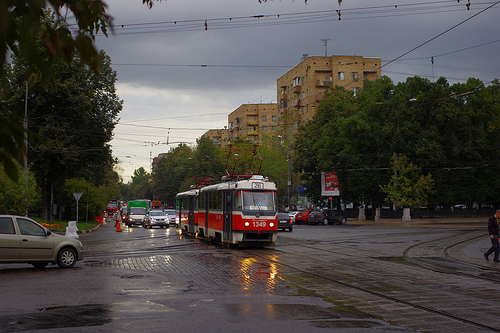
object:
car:
[125, 207, 147, 227]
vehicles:
[136, 198, 153, 211]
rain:
[142, 255, 418, 313]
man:
[483, 210, 499, 263]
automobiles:
[278, 213, 293, 232]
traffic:
[121, 168, 295, 251]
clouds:
[134, 32, 250, 58]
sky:
[143, 78, 236, 104]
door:
[223, 190, 233, 241]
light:
[178, 229, 182, 236]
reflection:
[264, 254, 279, 295]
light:
[195, 232, 199, 239]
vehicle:
[120, 205, 128, 223]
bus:
[175, 175, 278, 249]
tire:
[56, 248, 76, 268]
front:
[232, 175, 278, 247]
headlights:
[129, 217, 133, 221]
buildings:
[198, 129, 232, 154]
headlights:
[244, 222, 249, 227]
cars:
[163, 209, 176, 227]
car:
[0, 215, 84, 268]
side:
[0, 215, 84, 268]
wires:
[106, 0, 497, 36]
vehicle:
[307, 207, 347, 225]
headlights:
[269, 222, 275, 227]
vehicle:
[295, 209, 314, 225]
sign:
[72, 192, 83, 201]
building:
[278, 56, 381, 152]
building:
[225, 103, 282, 151]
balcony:
[292, 85, 301, 94]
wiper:
[255, 199, 264, 216]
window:
[242, 192, 276, 216]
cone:
[116, 222, 123, 232]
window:
[16, 219, 46, 236]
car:
[143, 210, 170, 229]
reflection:
[239, 257, 259, 290]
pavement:
[4, 271, 460, 331]